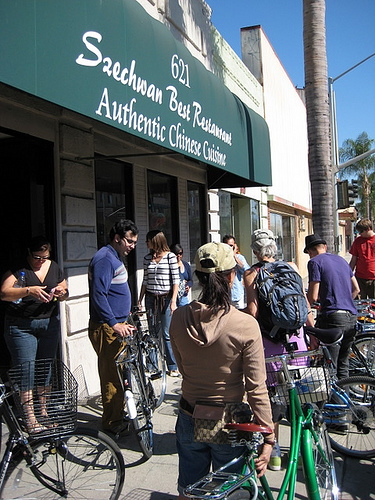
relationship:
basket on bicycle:
[5, 355, 80, 440] [0, 359, 127, 500]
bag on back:
[188, 391, 237, 453] [167, 308, 253, 418]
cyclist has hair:
[88, 218, 140, 437] [106, 218, 139, 242]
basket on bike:
[267, 347, 336, 415] [240, 375, 346, 482]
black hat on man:
[303, 232, 327, 253] [296, 225, 359, 402]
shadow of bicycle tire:
[83, 408, 193, 453] [28, 428, 139, 495]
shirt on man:
[92, 238, 133, 322] [87, 220, 151, 436]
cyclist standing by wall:
[0, 238, 70, 433] [0, 107, 95, 410]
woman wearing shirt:
[136, 230, 179, 378] [139, 250, 182, 296]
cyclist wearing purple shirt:
[303, 235, 360, 436] [307, 251, 358, 316]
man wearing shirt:
[353, 212, 373, 295] [348, 240, 373, 273]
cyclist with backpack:
[245, 228, 315, 473] [255, 269, 308, 330]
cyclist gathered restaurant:
[3, 360, 112, 492] [56, 25, 244, 197]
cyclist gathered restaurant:
[83, 222, 166, 449] [56, 25, 244, 197]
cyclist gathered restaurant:
[170, 241, 261, 498] [56, 25, 244, 197]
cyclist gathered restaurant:
[245, 230, 307, 388] [56, 25, 244, 197]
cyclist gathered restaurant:
[303, 235, 362, 391] [56, 25, 244, 197]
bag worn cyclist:
[191, 402, 234, 447] [167, 241, 275, 498]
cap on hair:
[194, 240, 237, 272] [191, 250, 239, 318]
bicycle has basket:
[182, 343, 339, 500] [259, 354, 327, 399]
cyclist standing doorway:
[0, 238, 70, 433] [0, 127, 63, 435]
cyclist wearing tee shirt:
[0, 238, 70, 433] [11, 258, 64, 318]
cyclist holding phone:
[0, 238, 70, 433] [45, 288, 54, 301]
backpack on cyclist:
[253, 259, 308, 343] [245, 228, 315, 473]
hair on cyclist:
[250, 227, 275, 260] [245, 228, 315, 473]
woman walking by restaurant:
[136, 230, 179, 378] [31, 4, 260, 176]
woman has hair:
[136, 230, 179, 378] [143, 226, 169, 256]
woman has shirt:
[136, 230, 179, 378] [143, 249, 172, 300]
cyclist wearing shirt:
[303, 235, 360, 436] [306, 259, 351, 313]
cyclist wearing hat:
[303, 235, 360, 436] [299, 230, 326, 251]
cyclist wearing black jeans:
[303, 235, 360, 436] [312, 309, 358, 405]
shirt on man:
[348, 237, 374, 281] [339, 215, 373, 295]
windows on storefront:
[139, 164, 214, 270] [0, 99, 210, 422]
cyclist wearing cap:
[167, 241, 275, 498] [194, 243, 236, 275]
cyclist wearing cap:
[245, 228, 315, 473] [248, 226, 277, 241]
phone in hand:
[43, 284, 52, 292] [29, 283, 67, 301]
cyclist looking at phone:
[0, 238, 70, 433] [44, 288, 53, 301]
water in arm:
[9, 268, 26, 310] [6, 274, 52, 310]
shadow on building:
[149, 2, 233, 93] [106, 2, 277, 235]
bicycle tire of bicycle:
[0, 428, 126, 500] [11, 327, 150, 496]